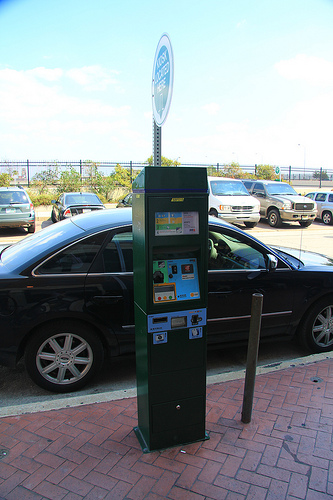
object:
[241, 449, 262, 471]
bricks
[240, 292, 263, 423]
pole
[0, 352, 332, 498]
sidewalk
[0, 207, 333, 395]
car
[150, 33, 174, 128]
street sign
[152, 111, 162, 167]
street pole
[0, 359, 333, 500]
ground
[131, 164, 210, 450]
machine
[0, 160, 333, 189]
fence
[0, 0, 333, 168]
sky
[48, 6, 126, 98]
sky